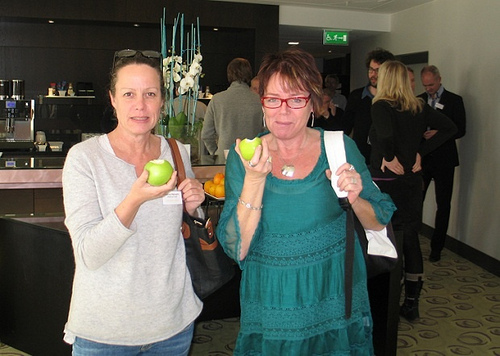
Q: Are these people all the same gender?
A: No, they are both male and female.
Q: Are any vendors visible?
A: No, there are no vendors.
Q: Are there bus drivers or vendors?
A: No, there are no vendors or bus drivers.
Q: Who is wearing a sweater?
A: The man is wearing a sweater.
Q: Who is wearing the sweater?
A: The man is wearing a sweater.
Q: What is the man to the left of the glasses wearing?
A: The man is wearing a sweater.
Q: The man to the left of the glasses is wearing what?
A: The man is wearing a sweater.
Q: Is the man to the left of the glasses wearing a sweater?
A: Yes, the man is wearing a sweater.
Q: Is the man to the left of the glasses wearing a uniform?
A: No, the man is wearing a sweater.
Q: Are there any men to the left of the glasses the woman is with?
A: Yes, there is a man to the left of the glasses.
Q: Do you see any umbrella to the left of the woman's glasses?
A: No, there is a man to the left of the glasses.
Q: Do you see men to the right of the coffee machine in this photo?
A: Yes, there is a man to the right of the coffee machine.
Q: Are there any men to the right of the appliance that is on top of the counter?
A: Yes, there is a man to the right of the coffee machine.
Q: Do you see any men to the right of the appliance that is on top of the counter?
A: Yes, there is a man to the right of the coffee machine.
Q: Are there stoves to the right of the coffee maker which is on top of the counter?
A: No, there is a man to the right of the coffee machine.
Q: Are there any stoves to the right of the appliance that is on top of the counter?
A: No, there is a man to the right of the coffee machine.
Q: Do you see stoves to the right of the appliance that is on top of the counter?
A: No, there is a man to the right of the coffee machine.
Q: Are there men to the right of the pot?
A: Yes, there is a man to the right of the pot.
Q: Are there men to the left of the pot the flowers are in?
A: No, the man is to the right of the pot.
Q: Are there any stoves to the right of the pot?
A: No, there is a man to the right of the pot.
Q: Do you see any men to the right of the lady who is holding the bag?
A: Yes, there is a man to the right of the lady.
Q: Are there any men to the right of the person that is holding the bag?
A: Yes, there is a man to the right of the lady.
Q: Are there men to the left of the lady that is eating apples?
A: No, the man is to the right of the lady.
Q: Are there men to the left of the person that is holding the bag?
A: No, the man is to the right of the lady.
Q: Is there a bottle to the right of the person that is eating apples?
A: No, there is a man to the right of the lady.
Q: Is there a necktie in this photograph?
A: No, there are no ties.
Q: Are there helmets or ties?
A: No, there are no ties or helmets.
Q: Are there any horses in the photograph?
A: No, there are no horses.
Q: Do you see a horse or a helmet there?
A: No, there are no horses or helmets.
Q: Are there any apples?
A: Yes, there is an apple.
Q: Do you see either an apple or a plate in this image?
A: Yes, there is an apple.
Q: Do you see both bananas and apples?
A: No, there is an apple but no bananas.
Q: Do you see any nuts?
A: No, there are no nuts.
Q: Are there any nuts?
A: No, there are no nuts.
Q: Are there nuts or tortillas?
A: No, there are no nuts or tortillas.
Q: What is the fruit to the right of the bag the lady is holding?
A: The fruit is an apple.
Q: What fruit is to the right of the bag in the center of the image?
A: The fruit is an apple.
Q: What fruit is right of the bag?
A: The fruit is an apple.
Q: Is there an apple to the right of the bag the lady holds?
A: Yes, there is an apple to the right of the bag.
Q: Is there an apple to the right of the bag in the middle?
A: Yes, there is an apple to the right of the bag.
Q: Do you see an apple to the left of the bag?
A: No, the apple is to the right of the bag.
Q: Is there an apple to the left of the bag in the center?
A: No, the apple is to the right of the bag.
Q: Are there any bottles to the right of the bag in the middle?
A: No, there is an apple to the right of the bag.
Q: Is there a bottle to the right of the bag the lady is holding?
A: No, there is an apple to the right of the bag.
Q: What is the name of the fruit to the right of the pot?
A: The fruit is an apple.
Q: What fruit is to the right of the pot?
A: The fruit is an apple.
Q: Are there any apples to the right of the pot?
A: Yes, there is an apple to the right of the pot.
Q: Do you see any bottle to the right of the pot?
A: No, there is an apple to the right of the pot.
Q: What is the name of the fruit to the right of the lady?
A: The fruit is an apple.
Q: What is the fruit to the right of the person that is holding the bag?
A: The fruit is an apple.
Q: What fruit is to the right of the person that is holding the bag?
A: The fruit is an apple.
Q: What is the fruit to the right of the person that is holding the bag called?
A: The fruit is an apple.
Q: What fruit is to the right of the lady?
A: The fruit is an apple.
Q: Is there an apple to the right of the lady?
A: Yes, there is an apple to the right of the lady.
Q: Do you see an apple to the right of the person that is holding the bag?
A: Yes, there is an apple to the right of the lady.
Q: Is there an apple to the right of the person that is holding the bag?
A: Yes, there is an apple to the right of the lady.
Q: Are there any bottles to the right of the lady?
A: No, there is an apple to the right of the lady.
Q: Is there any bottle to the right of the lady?
A: No, there is an apple to the right of the lady.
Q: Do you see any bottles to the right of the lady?
A: No, there is an apple to the right of the lady.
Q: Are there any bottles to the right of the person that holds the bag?
A: No, there is an apple to the right of the lady.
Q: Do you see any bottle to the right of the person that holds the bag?
A: No, there is an apple to the right of the lady.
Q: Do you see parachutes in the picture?
A: No, there are no parachutes.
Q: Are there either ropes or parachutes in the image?
A: No, there are no parachutes or ropes.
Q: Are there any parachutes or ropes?
A: No, there are no parachutes or ropes.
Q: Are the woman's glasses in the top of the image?
A: Yes, the glasses are in the top of the image.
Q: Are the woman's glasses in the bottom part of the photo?
A: No, the glasses are in the top of the image.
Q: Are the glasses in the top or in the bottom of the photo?
A: The glasses are in the top of the image.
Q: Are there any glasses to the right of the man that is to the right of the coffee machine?
A: Yes, there are glasses to the right of the man.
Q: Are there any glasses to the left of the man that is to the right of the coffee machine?
A: No, the glasses are to the right of the man.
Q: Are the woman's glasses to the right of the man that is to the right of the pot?
A: Yes, the glasses are to the right of the man.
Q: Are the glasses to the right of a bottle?
A: No, the glasses are to the right of the man.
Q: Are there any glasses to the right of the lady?
A: Yes, there are glasses to the right of the lady.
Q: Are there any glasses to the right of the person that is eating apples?
A: Yes, there are glasses to the right of the lady.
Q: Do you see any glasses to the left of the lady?
A: No, the glasses are to the right of the lady.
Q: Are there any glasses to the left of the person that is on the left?
A: No, the glasses are to the right of the lady.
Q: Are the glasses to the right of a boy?
A: No, the glasses are to the right of the lady.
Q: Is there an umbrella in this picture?
A: No, there are no umbrellas.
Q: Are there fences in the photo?
A: No, there are no fences.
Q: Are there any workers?
A: No, there are no workers.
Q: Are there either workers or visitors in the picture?
A: No, there are no workers or visitors.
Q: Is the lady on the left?
A: Yes, the lady is on the left of the image.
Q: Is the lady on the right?
A: No, the lady is on the left of the image.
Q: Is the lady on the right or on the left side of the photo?
A: The lady is on the left of the image.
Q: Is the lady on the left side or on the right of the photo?
A: The lady is on the left of the image.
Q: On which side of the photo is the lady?
A: The lady is on the left of the image.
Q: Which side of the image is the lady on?
A: The lady is on the left of the image.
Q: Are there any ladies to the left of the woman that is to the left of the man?
A: Yes, there is a lady to the left of the woman.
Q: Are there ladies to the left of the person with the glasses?
A: Yes, there is a lady to the left of the woman.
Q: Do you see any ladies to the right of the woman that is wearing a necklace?
A: No, the lady is to the left of the woman.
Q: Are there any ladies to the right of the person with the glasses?
A: No, the lady is to the left of the woman.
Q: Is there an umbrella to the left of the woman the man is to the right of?
A: No, there is a lady to the left of the woman.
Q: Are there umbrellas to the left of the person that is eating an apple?
A: No, there is a lady to the left of the woman.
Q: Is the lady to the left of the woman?
A: Yes, the lady is to the left of the woman.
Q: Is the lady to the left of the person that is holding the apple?
A: Yes, the lady is to the left of the woman.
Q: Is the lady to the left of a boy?
A: No, the lady is to the left of the woman.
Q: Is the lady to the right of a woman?
A: No, the lady is to the left of a woman.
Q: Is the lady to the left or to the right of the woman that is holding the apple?
A: The lady is to the left of the woman.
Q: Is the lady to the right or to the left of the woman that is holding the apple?
A: The lady is to the left of the woman.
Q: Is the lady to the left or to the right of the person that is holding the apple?
A: The lady is to the left of the woman.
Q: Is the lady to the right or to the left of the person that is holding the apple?
A: The lady is to the left of the woman.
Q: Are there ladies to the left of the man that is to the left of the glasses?
A: Yes, there is a lady to the left of the man.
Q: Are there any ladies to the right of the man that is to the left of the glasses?
A: No, the lady is to the left of the man.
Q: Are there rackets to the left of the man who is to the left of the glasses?
A: No, there is a lady to the left of the man.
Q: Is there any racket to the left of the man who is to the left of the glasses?
A: No, there is a lady to the left of the man.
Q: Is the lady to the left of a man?
A: Yes, the lady is to the left of a man.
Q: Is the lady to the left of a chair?
A: No, the lady is to the left of a man.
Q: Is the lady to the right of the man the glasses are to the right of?
A: No, the lady is to the left of the man.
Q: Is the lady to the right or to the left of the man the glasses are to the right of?
A: The lady is to the left of the man.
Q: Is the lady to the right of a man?
A: No, the lady is to the left of a man.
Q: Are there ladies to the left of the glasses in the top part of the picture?
A: Yes, there is a lady to the left of the glasses.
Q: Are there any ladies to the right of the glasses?
A: No, the lady is to the left of the glasses.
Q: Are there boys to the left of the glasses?
A: No, there is a lady to the left of the glasses.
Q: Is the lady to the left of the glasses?
A: Yes, the lady is to the left of the glasses.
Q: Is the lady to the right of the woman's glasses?
A: No, the lady is to the left of the glasses.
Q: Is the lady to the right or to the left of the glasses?
A: The lady is to the left of the glasses.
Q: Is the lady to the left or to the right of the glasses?
A: The lady is to the left of the glasses.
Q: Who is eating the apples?
A: The lady is eating the apples.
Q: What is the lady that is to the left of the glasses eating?
A: The lady is eating apples.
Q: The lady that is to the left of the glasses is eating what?
A: The lady is eating apples.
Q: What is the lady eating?
A: The lady is eating apples.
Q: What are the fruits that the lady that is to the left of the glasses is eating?
A: The fruits are apples.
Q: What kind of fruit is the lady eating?
A: The lady is eating apples.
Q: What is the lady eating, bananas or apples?
A: The lady is eating apples.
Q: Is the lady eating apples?
A: Yes, the lady is eating apples.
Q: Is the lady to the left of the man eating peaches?
A: No, the lady is eating apples.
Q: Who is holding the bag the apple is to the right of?
A: The lady is holding the bag.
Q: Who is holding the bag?
A: The lady is holding the bag.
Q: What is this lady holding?
A: The lady is holding the bag.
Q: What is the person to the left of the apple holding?
A: The lady is holding the bag.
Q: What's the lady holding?
A: The lady is holding the bag.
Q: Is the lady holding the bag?
A: Yes, the lady is holding the bag.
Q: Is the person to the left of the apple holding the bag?
A: Yes, the lady is holding the bag.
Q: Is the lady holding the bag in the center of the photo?
A: Yes, the lady is holding the bag.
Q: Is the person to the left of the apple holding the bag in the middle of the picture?
A: Yes, the lady is holding the bag.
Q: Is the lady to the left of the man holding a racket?
A: No, the lady is holding the bag.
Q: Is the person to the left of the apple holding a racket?
A: No, the lady is holding the bag.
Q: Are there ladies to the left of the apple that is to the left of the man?
A: Yes, there is a lady to the left of the apple.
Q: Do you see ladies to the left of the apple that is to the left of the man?
A: Yes, there is a lady to the left of the apple.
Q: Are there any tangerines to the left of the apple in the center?
A: No, there is a lady to the left of the apple.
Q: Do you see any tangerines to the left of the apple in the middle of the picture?
A: No, there is a lady to the left of the apple.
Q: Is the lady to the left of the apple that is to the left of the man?
A: Yes, the lady is to the left of the apple.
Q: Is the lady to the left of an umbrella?
A: No, the lady is to the left of the apple.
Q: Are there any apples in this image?
A: Yes, there are apples.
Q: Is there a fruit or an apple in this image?
A: Yes, there are apples.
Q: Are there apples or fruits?
A: Yes, there are apples.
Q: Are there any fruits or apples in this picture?
A: Yes, there are apples.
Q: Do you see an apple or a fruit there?
A: Yes, there are apples.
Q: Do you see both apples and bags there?
A: Yes, there are both apples and a bag.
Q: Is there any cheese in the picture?
A: No, there is no cheese.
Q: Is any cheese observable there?
A: No, there is no cheese.